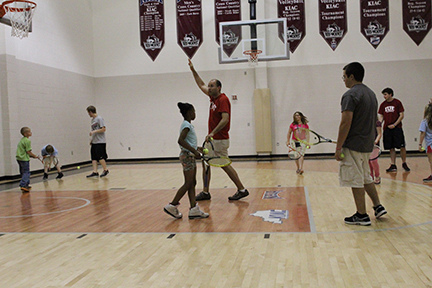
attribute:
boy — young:
[13, 119, 40, 191]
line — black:
[168, 227, 177, 241]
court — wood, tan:
[3, 157, 429, 286]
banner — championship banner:
[138, 0, 164, 61]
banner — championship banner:
[176, 0, 203, 59]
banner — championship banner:
[319, 0, 347, 48]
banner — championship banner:
[360, 0, 388, 48]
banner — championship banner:
[402, 0, 430, 46]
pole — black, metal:
[249, 0, 258, 57]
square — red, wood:
[0, 184, 309, 230]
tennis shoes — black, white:
[344, 201, 387, 225]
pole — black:
[245, 6, 265, 62]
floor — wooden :
[2, 151, 429, 285]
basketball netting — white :
[3, 0, 45, 43]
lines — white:
[6, 193, 105, 230]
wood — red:
[2, 196, 332, 228]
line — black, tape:
[262, 231, 272, 241]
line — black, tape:
[165, 233, 176, 240]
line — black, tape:
[76, 233, 90, 240]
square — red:
[0, 188, 313, 234]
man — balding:
[152, 69, 250, 244]